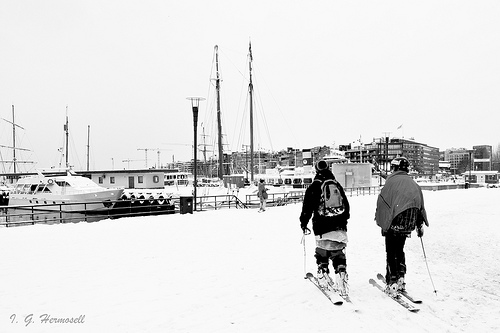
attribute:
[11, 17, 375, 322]
photo — white, black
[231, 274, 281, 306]
snow — abundant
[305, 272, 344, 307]
skis — a pair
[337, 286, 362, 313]
skis — a pair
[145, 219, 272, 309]
snow — white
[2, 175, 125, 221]
boat — white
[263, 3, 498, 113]
sky — grey, cold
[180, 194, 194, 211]
can — trash can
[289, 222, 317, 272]
pole — a ski pole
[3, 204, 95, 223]
water — very cold